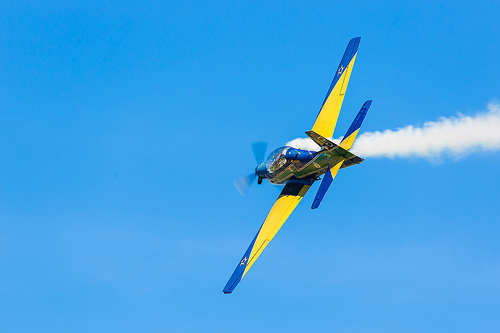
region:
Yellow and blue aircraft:
[216, 35, 372, 295]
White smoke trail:
[333, 103, 499, 158]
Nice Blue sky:
[28, 33, 186, 224]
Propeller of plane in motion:
[228, 135, 271, 196]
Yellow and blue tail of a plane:
[313, 95, 374, 210]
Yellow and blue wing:
[223, 174, 319, 299]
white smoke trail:
[292, 102, 498, 160]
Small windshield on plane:
[263, 143, 286, 165]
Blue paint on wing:
[334, 30, 361, 72]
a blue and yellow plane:
[173, 52, 385, 311]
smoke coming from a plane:
[376, 100, 478, 202]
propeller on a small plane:
[207, 139, 279, 196]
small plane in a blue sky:
[146, 53, 451, 300]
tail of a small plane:
[297, 128, 373, 217]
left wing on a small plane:
[176, 189, 298, 296]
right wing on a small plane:
[280, 20, 362, 137]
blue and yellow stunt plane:
[210, 32, 375, 292]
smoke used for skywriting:
[277, 82, 470, 230]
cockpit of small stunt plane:
[232, 137, 303, 186]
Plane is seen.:
[225, 97, 395, 220]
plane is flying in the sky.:
[226, 80, 366, 237]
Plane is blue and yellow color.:
[230, 85, 410, 265]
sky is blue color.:
[46, 110, 191, 320]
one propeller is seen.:
[230, 135, 271, 195]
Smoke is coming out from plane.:
[295, 120, 495, 175]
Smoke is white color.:
[367, 121, 487, 157]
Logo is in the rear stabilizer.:
[300, 125, 365, 160]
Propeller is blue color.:
[245, 130, 266, 195]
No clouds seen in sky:
[24, 87, 228, 255]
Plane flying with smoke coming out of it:
[183, 31, 499, 314]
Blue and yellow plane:
[195, 4, 495, 305]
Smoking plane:
[198, 1, 499, 297]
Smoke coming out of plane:
[191, 31, 491, 316]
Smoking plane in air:
[183, 20, 498, 309]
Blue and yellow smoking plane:
[202, 29, 499, 294]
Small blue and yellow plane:
[183, 34, 468, 322]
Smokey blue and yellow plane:
[177, 25, 492, 314]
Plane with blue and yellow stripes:
[190, 28, 498, 311]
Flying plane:
[174, 26, 489, 301]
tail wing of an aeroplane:
[306, 131, 361, 161]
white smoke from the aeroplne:
[399, 120, 476, 141]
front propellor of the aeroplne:
[237, 147, 265, 190]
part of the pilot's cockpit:
[265, 148, 281, 168]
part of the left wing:
[221, 240, 261, 296]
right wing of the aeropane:
[318, 36, 363, 118]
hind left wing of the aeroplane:
[310, 170, 348, 196]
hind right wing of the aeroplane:
[342, 115, 357, 147]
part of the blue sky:
[48, 86, 195, 263]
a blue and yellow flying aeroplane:
[211, 35, 357, 272]